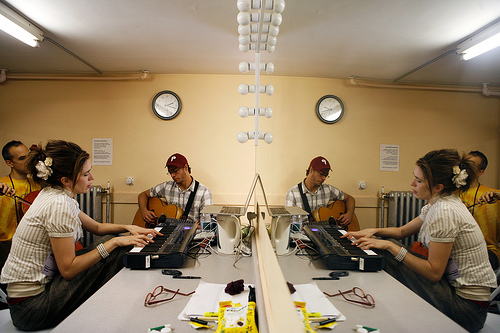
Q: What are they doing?
A: Making music.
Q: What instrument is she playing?
A: Keyboard.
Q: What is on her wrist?
A: Braclet.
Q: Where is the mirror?
A: On the right.